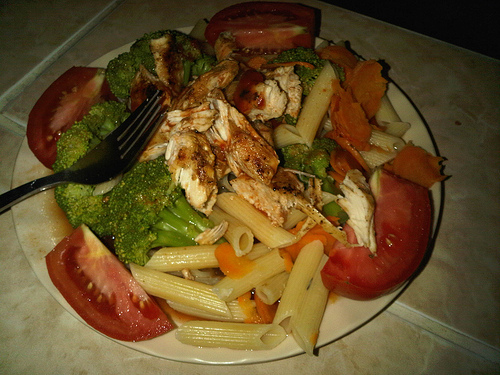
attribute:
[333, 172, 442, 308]
tomato — slice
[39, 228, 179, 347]
tomato — slice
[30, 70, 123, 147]
tomato — slice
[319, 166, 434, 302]
tomato — chopped, red, cut-up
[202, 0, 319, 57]
tomato — chopped, slice, fresh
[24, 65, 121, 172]
tomato — chopped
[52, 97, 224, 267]
broccoli — cooked 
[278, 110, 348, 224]
broccoli — cooked 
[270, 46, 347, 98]
broccoli — cooked 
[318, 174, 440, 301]
tomato — red 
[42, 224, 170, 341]
tomato — chopped, red , cut-up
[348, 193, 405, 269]
tomato — red, cut-up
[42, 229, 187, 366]
tomato — red 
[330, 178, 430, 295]
tomato — red, cut-up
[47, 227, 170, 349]
tomato — cut-up, red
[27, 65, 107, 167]
tomato — cut-up, red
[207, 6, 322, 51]
tomato — cut-up, red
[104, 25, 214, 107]
broccoli — cooked , green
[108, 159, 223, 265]
broccoli — green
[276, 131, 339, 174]
broccoli — green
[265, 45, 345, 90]
broccoli — green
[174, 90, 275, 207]
chicken — brown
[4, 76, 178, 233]
silverware — silver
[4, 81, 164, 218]
fork — stainless,  steel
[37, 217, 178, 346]
tomato — red, cut-up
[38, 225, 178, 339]
tomato — glistening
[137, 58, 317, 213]
chicken — grilled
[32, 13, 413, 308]
tomato — sliced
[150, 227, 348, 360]
noodles — cooked, penne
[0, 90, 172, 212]
fork — silver,  steel, Stainless, roasted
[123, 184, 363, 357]
pasta — penne 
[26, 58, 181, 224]
fork — silver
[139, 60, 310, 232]
chicken — oven-roasted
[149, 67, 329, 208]
chicken — shredded 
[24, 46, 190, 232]
fork — metal